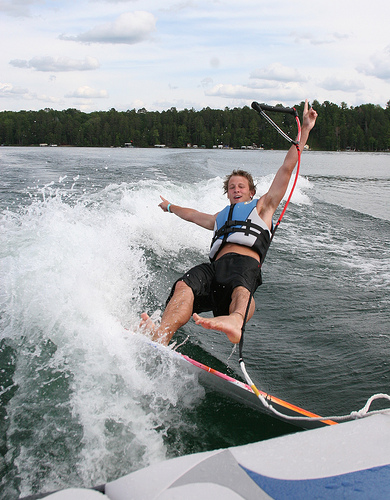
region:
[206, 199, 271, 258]
A blue and grey life jacket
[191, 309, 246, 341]
A human foot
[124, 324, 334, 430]
A pink and orange skiing board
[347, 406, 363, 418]
A knot in a white rope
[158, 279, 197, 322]
A hairy male leg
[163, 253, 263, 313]
A pair of black swimming shorts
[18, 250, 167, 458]
White spray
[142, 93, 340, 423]
A man water boarding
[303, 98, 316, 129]
A hand with one finger raised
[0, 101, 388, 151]
A line of dark green trees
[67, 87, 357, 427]
man falling into the water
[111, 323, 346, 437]
wakeboard sideways in the water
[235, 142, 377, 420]
white, black, and red cord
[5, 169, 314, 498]
wake from the boat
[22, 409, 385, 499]
back of a boat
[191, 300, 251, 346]
foot in the air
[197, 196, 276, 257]
blue, silver, and black life jacket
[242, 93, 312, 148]
handlebar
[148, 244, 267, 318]
wet black shorts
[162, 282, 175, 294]
tiny drop of water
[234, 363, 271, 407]
A white rope above the water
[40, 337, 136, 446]
The water is splashing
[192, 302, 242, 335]
The left foot of the man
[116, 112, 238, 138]
Trees beyond the water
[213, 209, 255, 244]
A lifevest on the man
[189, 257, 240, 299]
The man's shorts are black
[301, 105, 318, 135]
The left hand of the man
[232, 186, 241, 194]
The nose of the man on the water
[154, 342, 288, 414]
A board on top of the water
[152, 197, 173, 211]
The right hand of the man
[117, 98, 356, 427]
boy falling off of water board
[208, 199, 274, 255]
blue white and black life jacket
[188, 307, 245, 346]
foot of man skiing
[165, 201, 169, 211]
blue bracelet on wrist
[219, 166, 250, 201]
face of man skiing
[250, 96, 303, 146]
hand on ski rope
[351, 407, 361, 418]
knot on ski rope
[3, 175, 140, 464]
wake from boat on water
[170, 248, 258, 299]
black shorts on man skiing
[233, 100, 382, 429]
ski rope attached to boat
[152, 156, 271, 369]
A man is having fun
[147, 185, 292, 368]
The man is behind a boat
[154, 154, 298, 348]
The man is in the air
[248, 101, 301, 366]
The man let go of the tow ropes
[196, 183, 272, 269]
The man is wearing a life jacket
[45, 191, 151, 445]
The boat leaves a wake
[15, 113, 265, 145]
Tall trees in the background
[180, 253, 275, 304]
The man is wearing shorts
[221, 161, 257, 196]
The man has short hair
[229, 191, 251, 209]
The man's mouth is open